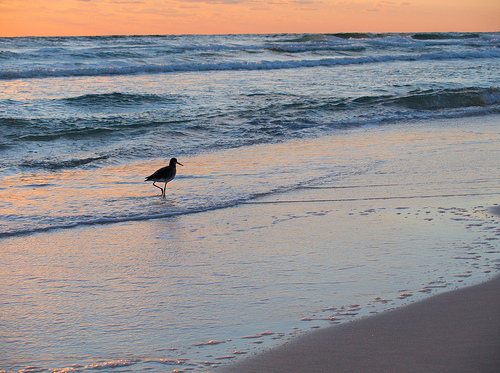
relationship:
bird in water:
[143, 157, 191, 203] [4, 36, 498, 155]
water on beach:
[4, 36, 498, 155] [225, 290, 500, 371]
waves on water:
[269, 32, 367, 57] [4, 36, 498, 155]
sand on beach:
[424, 308, 482, 350] [225, 290, 500, 371]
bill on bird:
[176, 158, 185, 168] [143, 157, 191, 203]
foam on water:
[369, 33, 416, 42] [4, 36, 498, 155]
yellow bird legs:
[158, 188, 166, 194] [148, 179, 170, 200]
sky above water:
[2, 2, 498, 32] [4, 36, 498, 155]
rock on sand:
[452, 249, 484, 268] [424, 308, 482, 350]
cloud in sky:
[293, 11, 340, 26] [2, 2, 498, 32]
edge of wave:
[286, 60, 498, 69] [271, 39, 367, 52]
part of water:
[258, 34, 313, 43] [4, 36, 498, 155]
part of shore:
[258, 34, 313, 43] [263, 203, 499, 225]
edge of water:
[286, 60, 498, 69] [4, 36, 498, 155]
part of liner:
[258, 34, 313, 43] [226, 192, 480, 203]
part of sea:
[258, 34, 313, 43] [2, 36, 496, 69]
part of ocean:
[258, 34, 313, 43] [2, 38, 496, 143]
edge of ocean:
[286, 60, 498, 69] [2, 38, 496, 143]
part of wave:
[258, 34, 313, 43] [271, 39, 367, 52]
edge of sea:
[286, 60, 498, 69] [2, 36, 496, 69]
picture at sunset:
[6, 7, 497, 203] [2, 4, 497, 51]